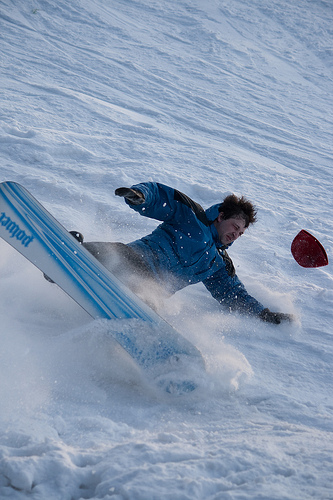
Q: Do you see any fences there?
A: No, there are no fences.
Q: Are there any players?
A: No, there are no players.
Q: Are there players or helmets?
A: No, there are no players or helmets.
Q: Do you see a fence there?
A: No, there are no fences.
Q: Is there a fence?
A: No, there are no fences.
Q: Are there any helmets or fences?
A: No, there are no fences or helmets.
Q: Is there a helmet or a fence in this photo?
A: No, there are no fences or helmets.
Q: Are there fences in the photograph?
A: No, there are no fences.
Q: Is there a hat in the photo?
A: Yes, there is a hat.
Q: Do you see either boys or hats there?
A: Yes, there is a hat.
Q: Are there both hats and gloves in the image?
A: Yes, there are both a hat and gloves.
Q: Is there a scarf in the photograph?
A: No, there are no scarves.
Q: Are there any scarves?
A: No, there are no scarves.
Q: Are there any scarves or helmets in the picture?
A: No, there are no scarves or helmets.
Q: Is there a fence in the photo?
A: No, there are no fences.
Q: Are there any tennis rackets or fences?
A: No, there are no fences or tennis rackets.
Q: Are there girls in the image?
A: No, there are no girls.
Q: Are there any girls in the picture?
A: No, there are no girls.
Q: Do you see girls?
A: No, there are no girls.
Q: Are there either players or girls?
A: No, there are no girls or players.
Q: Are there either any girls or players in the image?
A: No, there are no girls or players.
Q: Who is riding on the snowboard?
A: The man is riding on the snowboard.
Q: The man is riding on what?
A: The man is riding on the snowboard.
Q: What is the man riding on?
A: The man is riding on the snowboard.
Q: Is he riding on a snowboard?
A: Yes, the man is riding on a snowboard.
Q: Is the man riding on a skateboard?
A: No, the man is riding on a snowboard.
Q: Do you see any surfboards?
A: No, there are no surfboards.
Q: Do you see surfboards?
A: No, there are no surfboards.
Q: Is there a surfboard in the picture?
A: No, there are no surfboards.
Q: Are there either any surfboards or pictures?
A: No, there are no surfboards or pictures.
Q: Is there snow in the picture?
A: Yes, there is snow.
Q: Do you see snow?
A: Yes, there is snow.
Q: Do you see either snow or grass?
A: Yes, there is snow.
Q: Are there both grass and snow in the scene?
A: No, there is snow but no grass.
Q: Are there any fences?
A: No, there are no fences.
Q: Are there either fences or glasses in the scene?
A: No, there are no fences or glasses.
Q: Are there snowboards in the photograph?
A: Yes, there is a snowboard.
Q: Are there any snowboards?
A: Yes, there is a snowboard.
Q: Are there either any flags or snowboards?
A: Yes, there is a snowboard.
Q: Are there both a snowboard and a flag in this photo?
A: No, there is a snowboard but no flags.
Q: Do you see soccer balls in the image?
A: No, there are no soccer balls.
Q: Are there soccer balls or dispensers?
A: No, there are no soccer balls or dispensers.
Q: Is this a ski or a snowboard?
A: This is a snowboard.